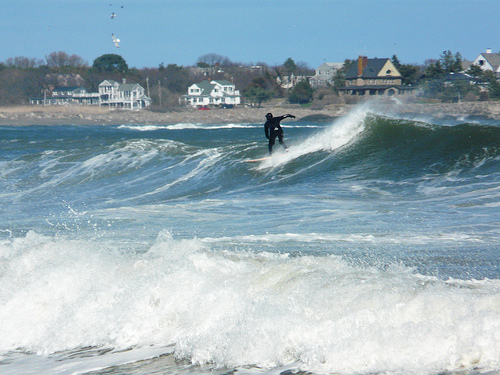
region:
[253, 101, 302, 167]
a surfer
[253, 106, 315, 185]
a surfer in a black body suit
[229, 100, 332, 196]
a man surfing in the ocean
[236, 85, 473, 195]
a man surfing a large wave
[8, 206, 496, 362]
a large wave in the ocean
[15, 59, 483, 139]
a row of houses by the beach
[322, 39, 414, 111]
a house by the beach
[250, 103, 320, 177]
a man holding his arm out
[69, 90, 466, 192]
a surfer on a wave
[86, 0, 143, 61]
a group of birds in the sky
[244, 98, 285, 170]
surfer in wet suit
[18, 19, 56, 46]
white clouds in blue sky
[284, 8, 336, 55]
white clouds in blue sky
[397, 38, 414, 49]
white clouds in blue sky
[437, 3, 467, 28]
white clouds in blue sky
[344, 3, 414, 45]
white clouds in blue sky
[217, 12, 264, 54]
white clouds in blue sky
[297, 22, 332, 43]
white clouds in blue sky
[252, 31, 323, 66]
white clouds in blue sky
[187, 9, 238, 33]
white clouds in blue sky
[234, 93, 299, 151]
surfer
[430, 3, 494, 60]
white clouds in blue sky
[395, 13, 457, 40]
white clouds in blue sky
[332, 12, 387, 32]
white clouds in blue sky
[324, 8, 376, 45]
white clouds in blue sky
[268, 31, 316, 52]
white clouds in blue sky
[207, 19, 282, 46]
white clouds in blue sky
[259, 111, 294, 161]
surfer rides wave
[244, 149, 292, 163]
surfboard rides wave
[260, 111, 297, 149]
surfer is on surfboard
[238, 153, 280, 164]
surfboard has surfer on it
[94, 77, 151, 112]
house is in background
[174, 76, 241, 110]
house is in background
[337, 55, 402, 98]
house is in background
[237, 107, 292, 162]
surfer wears wetsuit in order to keep warm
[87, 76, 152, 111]
house is on beach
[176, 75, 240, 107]
house is on beach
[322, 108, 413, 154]
CREST OF HIGH WAVE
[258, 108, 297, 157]
SURFER IN OCEAN WAVE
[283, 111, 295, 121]
HAND OF ATHLETIC SURFER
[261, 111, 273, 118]
HEAD OF ATHLETIC SURFER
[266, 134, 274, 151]
LEG OF ATHLETIC SURFER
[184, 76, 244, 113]
LARGE HOME BY SEASHORE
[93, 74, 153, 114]
LARGE HOME BY SEASHORE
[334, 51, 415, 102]
LARGE HOME BY SEASHORE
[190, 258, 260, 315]
CHURNING WHITE OCEAN SURF